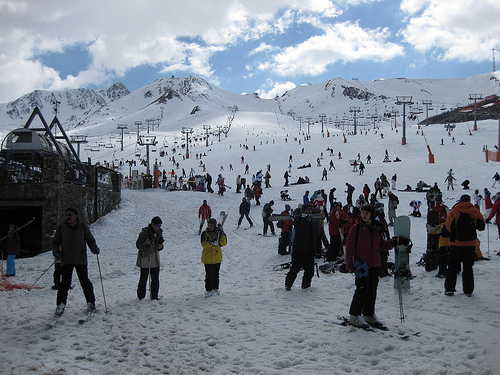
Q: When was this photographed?
A: Day time.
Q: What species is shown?
A: Human.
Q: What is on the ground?
A: Snow.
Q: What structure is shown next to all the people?
A: Ski lifts.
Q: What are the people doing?
A: Skiing.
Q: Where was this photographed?
A: Mountain.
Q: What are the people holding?
A: Ski poles.